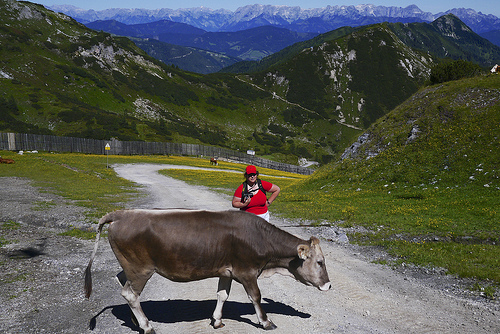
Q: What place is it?
A: It is a path.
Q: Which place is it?
A: It is a path.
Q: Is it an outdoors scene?
A: Yes, it is outdoors.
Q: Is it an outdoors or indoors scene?
A: It is outdoors.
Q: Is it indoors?
A: No, it is outdoors.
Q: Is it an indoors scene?
A: No, it is outdoors.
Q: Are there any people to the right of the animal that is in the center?
A: Yes, there is a person to the right of the animal.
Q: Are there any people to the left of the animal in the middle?
A: No, the person is to the right of the animal.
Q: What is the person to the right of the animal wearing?
A: The person is wearing a shirt.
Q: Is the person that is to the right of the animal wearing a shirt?
A: Yes, the person is wearing a shirt.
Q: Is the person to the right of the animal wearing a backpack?
A: No, the person is wearing a shirt.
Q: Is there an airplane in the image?
A: No, there are no airplanes.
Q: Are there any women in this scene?
A: Yes, there is a woman.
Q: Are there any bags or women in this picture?
A: Yes, there is a woman.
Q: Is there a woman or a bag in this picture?
A: Yes, there is a woman.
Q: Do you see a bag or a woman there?
A: Yes, there is a woman.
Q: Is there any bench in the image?
A: No, there are no benches.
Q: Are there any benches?
A: No, there are no benches.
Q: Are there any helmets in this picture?
A: No, there are no helmets.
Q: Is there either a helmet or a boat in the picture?
A: No, there are no helmets or boats.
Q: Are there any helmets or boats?
A: No, there are no helmets or boats.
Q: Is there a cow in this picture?
A: Yes, there is a cow.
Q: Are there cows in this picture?
A: Yes, there is a cow.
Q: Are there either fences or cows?
A: Yes, there is a cow.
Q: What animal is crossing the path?
A: The cow is crossing the path.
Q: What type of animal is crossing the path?
A: The animal is a cow.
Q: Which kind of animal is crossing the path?
A: The animal is a cow.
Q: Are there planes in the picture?
A: No, there are no planes.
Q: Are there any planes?
A: No, there are no planes.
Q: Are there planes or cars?
A: No, there are no planes or cars.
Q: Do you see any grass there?
A: Yes, there is grass.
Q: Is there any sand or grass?
A: Yes, there is grass.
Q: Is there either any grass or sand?
A: Yes, there is grass.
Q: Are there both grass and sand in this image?
A: No, there is grass but no sand.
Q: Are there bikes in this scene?
A: No, there are no bikes.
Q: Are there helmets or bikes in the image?
A: No, there are no bikes or helmets.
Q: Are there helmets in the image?
A: No, there are no helmets.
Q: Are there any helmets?
A: No, there are no helmets.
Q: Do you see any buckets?
A: No, there are no buckets.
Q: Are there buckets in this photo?
A: No, there are no buckets.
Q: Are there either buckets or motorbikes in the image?
A: No, there are no buckets or motorbikes.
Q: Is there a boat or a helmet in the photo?
A: No, there are no helmets or boats.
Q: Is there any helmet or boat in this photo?
A: No, there are no helmets or boats.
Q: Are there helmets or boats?
A: No, there are no helmets or boats.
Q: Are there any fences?
A: Yes, there is a fence.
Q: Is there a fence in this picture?
A: Yes, there is a fence.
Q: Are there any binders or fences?
A: Yes, there is a fence.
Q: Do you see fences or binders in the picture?
A: Yes, there is a fence.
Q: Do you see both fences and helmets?
A: No, there is a fence but no helmets.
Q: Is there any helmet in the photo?
A: No, there are no helmets.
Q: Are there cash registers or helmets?
A: No, there are no helmets or cash registers.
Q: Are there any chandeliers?
A: No, there are no chandeliers.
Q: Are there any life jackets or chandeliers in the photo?
A: No, there are no chandeliers or life jackets.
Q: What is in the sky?
A: The clouds are in the sky.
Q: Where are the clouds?
A: The clouds are in the sky.